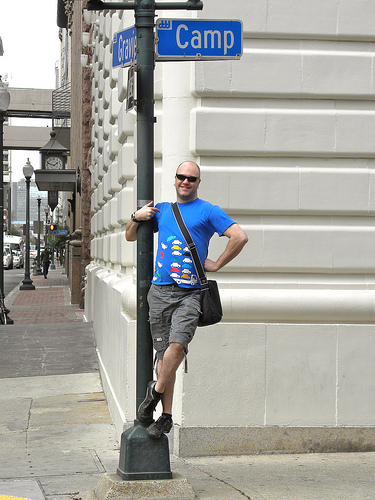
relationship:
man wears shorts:
[124, 160, 248, 441] [141, 282, 205, 348]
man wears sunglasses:
[124, 160, 248, 441] [175, 173, 196, 178]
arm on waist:
[201, 199, 255, 271] [148, 273, 210, 295]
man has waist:
[124, 160, 248, 441] [148, 273, 210, 295]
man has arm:
[124, 160, 248, 441] [201, 199, 255, 271]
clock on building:
[44, 156, 66, 171] [33, 1, 95, 301]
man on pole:
[124, 160, 248, 441] [133, 0, 157, 416]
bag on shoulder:
[198, 271, 260, 321] [192, 196, 260, 241]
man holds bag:
[124, 160, 248, 441] [198, 271, 260, 321]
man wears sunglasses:
[124, 160, 248, 441] [171, 164, 209, 189]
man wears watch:
[122, 157, 259, 446] [123, 200, 142, 233]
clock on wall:
[44, 156, 63, 171] [66, 104, 91, 208]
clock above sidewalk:
[44, 156, 63, 171] [16, 291, 85, 475]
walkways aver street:
[2, 84, 75, 153] [3, 257, 28, 282]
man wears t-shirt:
[124, 160, 248, 441] [151, 197, 237, 288]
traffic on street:
[4, 227, 35, 267] [3, 257, 28, 296]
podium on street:
[88, 470, 198, 498] [1, 228, 46, 338]